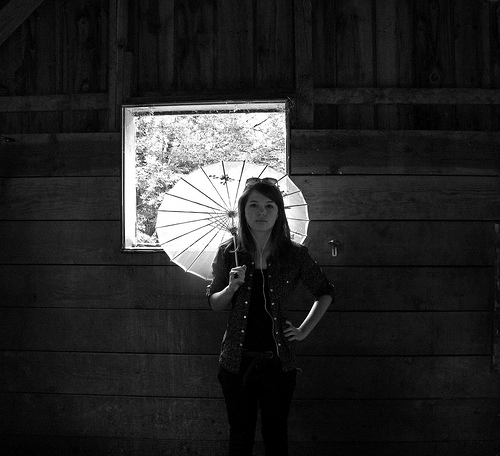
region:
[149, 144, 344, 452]
a woman holding an umbrella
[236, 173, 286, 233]
the head of a woman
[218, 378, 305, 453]
the legs of a woman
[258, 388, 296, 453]
the leg of a woman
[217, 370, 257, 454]
the leg of a woman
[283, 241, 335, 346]
the arm of a woman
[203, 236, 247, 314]
the arm of a woman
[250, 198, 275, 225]
the face of a woman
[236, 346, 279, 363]
the belt of a woman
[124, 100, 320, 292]
a woman standing in front of a window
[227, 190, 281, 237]
face of the woman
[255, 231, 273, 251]
neck of the woman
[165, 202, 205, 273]
the parasol behind the woman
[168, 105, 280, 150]
trees outside the window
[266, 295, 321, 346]
arm of the woman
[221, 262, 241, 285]
hand of the woman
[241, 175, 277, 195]
sunglasses on woman's head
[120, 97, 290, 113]
top of the window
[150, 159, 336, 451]
Person holding an umbrella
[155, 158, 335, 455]
Person holding an umbrella wearing a jacket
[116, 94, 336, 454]
Person standing in front of a window holding an umbrella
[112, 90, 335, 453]
Woman standing in front of a window holding an umbrella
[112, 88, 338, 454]
Lady holding an umbrella in front of a window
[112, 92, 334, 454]
Woman holding an umbrella in front of a window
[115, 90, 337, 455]
Person holding an umbrella in front of a window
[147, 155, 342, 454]
Lady in front of a wood wall holding an umbrella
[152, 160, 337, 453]
Woman in front of a wood wall holding an umbrella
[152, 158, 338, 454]
Person in front of a wood wall holding an umbrella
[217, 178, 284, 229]
face of the girl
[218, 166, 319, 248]
face of the hot girl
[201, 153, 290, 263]
face of the cute girl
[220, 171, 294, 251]
face of the young girl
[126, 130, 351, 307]
a girl holding umbrella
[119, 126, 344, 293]
a white umbrella holding by girl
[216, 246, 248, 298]
hand of the girl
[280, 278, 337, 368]
a girl placer her hand on hip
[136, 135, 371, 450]
a young girl standing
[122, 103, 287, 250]
a window shining light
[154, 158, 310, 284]
oriental style umbrella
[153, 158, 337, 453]
woman holding umbrella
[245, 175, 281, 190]
pair of sunglasses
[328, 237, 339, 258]
coat hook on wall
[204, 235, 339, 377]
long sleeved button up shirt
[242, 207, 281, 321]
a cord for earbuds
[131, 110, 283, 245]
Trees outside the window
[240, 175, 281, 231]
a womans face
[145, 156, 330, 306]
a woman holding an umbrella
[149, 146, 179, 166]
leaves on the tree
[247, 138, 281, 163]
leaves on the tree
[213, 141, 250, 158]
leaves on the tree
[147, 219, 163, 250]
leaves on the tree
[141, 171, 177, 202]
leaves on the tree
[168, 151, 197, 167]
leaves on the tree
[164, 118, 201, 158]
leaves on the tree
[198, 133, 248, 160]
leaves on the tree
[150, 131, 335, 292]
a white umbrella that is open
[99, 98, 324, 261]
a square box window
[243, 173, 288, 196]
a pair of sunglasses on a girls head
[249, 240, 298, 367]
a white colored headphone wire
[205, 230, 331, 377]
a button up shirt